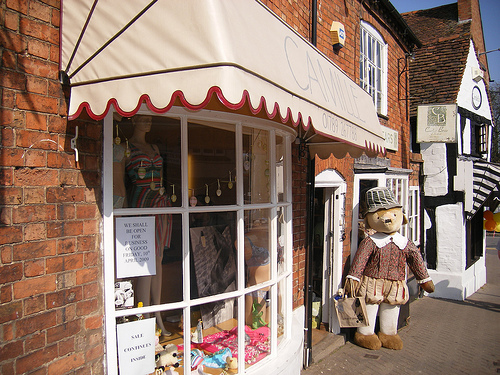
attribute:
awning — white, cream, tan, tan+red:
[53, 0, 393, 161]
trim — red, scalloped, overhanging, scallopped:
[66, 84, 389, 160]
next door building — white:
[408, 37, 499, 304]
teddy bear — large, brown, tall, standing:
[331, 181, 437, 356]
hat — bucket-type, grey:
[359, 182, 404, 218]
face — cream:
[364, 206, 405, 236]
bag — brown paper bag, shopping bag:
[331, 275, 371, 330]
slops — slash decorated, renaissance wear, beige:
[355, 273, 412, 309]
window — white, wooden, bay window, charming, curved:
[101, 97, 309, 373]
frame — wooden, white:
[102, 99, 290, 373]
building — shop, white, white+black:
[402, 1, 497, 304]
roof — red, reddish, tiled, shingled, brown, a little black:
[403, 33, 497, 125]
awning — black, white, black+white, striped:
[458, 157, 499, 221]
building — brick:
[1, 0, 412, 374]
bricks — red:
[0, 0, 424, 374]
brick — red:
[44, 187, 87, 205]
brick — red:
[14, 310, 59, 339]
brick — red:
[23, 331, 47, 353]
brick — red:
[44, 315, 84, 349]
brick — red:
[57, 337, 75, 357]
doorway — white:
[310, 165, 348, 342]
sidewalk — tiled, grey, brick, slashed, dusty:
[300, 254, 499, 375]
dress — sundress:
[122, 136, 175, 254]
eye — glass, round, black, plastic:
[392, 210, 399, 218]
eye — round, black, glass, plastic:
[376, 215, 383, 222]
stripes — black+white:
[464, 162, 500, 222]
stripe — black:
[472, 163, 499, 176]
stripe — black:
[473, 171, 499, 187]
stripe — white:
[473, 168, 499, 183]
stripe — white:
[472, 200, 485, 208]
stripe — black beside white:
[473, 180, 493, 196]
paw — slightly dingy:
[418, 278, 436, 297]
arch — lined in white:
[316, 168, 346, 186]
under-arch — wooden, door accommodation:
[314, 166, 349, 188]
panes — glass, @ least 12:
[113, 112, 289, 372]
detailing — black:
[407, 102, 484, 274]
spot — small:
[338, 363, 348, 371]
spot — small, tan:
[342, 357, 350, 364]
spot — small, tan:
[331, 361, 338, 370]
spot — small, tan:
[316, 366, 323, 373]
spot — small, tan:
[415, 366, 427, 373]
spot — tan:
[324, 364, 331, 374]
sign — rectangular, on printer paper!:
[113, 315, 163, 374]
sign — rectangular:
[114, 214, 159, 281]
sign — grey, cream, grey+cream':
[414, 103, 459, 147]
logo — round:
[338, 298, 366, 327]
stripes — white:
[365, 186, 398, 210]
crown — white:
[364, 183, 393, 194]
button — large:
[388, 236, 395, 242]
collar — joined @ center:
[362, 229, 410, 250]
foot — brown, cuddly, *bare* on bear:
[375, 329, 405, 353]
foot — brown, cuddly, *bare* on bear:
[351, 328, 384, 354]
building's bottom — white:
[223, 305, 305, 375]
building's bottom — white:
[420, 266, 489, 301]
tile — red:
[428, 79, 439, 86]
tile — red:
[426, 61, 436, 67]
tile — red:
[423, 50, 434, 57]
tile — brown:
[452, 42, 462, 50]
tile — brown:
[437, 96, 446, 103]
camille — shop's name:
[277, 33, 369, 124]